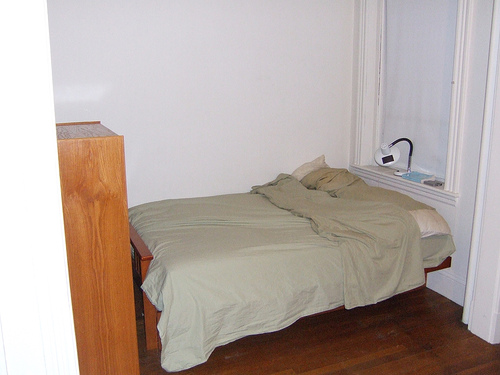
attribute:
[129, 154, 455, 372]
bed — made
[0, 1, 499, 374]
room — bedroom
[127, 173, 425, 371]
blanket — green, light green, gray, grey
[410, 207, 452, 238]
pillow — white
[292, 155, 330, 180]
pillow — white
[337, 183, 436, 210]
pillow case — green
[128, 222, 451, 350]
bed frame — wooden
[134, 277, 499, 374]
floor — wooden, brown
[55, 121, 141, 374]
shelf stand — wooden, brown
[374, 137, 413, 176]
lamp — white, bent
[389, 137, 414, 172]
gooseneck — black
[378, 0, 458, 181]
shade — white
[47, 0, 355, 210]
wall — white